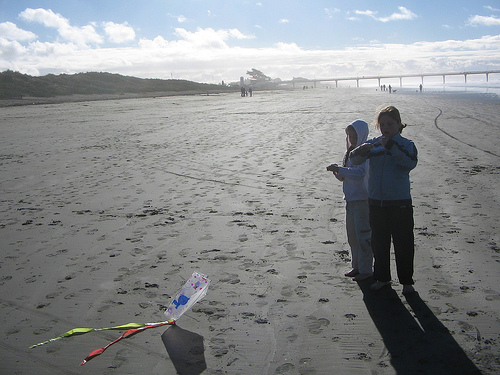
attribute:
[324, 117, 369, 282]
child — little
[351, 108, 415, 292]
child — little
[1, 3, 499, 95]
sky — cloudy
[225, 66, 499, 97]
bridge — long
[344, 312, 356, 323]
footprint — muddy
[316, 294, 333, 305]
footprint — muddy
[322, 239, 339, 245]
footprint — muddy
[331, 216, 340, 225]
footprint — muddy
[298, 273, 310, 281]
footprint — muddy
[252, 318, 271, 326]
footprint — muddy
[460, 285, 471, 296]
footprint — muddy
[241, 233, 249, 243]
footprint — muddy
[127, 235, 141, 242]
footprint — muddy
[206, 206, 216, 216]
footprint — muddy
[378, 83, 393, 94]
people — distant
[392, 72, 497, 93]
water — background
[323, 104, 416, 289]
barefoot girls — standing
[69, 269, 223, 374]
kite — on sand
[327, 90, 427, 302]
family — on sand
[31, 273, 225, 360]
kite — on sand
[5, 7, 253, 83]
clouds — white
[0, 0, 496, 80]
sky — cloudy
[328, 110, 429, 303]
people — standing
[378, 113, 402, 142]
face — on sand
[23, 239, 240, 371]
kite — on sand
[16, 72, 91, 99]
hill — background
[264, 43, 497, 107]
bridge — long, narrow, white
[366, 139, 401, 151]
stripes — on sand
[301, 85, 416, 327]
girl — on sand